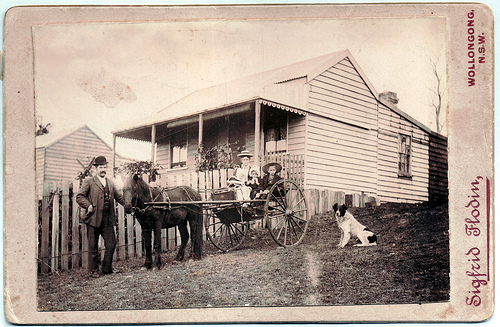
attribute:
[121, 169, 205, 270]
horse — pictured, small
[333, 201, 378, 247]
dog — sitting, spotted, black, white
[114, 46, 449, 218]
house — old, modest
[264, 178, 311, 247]
wheel — large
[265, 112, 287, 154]
window — glass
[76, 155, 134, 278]
man — standing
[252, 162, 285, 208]
child — sitting, home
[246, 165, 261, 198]
child — sitting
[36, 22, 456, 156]
sky — cloudy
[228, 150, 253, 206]
mother — sitting, wearing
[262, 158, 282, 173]
hat — wide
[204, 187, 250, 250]
wheel — large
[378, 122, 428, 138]
slat — wooden